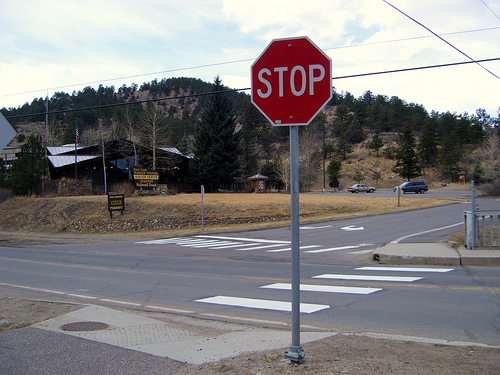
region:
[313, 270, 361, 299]
this is a zebra crossing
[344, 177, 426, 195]
cars on the road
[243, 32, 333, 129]
this is a sign post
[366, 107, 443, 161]
these are some trees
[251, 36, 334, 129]
the signpost is octagonal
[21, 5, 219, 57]
this is the sky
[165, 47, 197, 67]
the sky is blue in color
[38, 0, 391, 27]
the sky has clouds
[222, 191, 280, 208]
the ground is sandy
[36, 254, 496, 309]
the road is clear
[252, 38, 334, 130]
a red octagonal stop sign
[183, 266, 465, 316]
a cross walk painted white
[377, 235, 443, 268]
a cement curb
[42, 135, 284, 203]
a building across the street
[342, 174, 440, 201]
two cars in a parking lot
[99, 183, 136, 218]
a sign on the side of the road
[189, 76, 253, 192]
a big green pine tree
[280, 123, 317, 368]
a gray metal pole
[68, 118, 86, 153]
an American flag on a pole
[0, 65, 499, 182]
a hill in the background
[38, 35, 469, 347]
intersection in rural area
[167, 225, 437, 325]
thick white stripes on crosswalks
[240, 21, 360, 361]
red and white sign on pole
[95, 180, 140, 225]
small framed sign set into ground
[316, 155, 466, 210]
a couple of parked cars in lot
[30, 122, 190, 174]
triangular pieces of roofing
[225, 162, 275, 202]
informational kiosk at edge of lot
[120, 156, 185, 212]
yellow and black sign in front of building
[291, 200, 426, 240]
white arrows on street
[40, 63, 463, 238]
hill in back of building and lot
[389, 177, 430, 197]
a black car in a distance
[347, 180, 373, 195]
a car driving away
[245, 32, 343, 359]
a big stop sign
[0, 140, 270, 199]
a nice house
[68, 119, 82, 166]
an american flag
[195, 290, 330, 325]
a white line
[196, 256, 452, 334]
a zebra crossing sign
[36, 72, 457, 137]
a hill with trees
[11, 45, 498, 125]
an overhead wire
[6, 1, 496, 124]
a blue sky with some clouds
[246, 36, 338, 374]
a stop sign at an intersection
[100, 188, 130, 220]
a small sign in the grass by the road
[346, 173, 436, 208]
two cars parked in a lot in the distance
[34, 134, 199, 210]
a large business building across the street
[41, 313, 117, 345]
a round manhole in the middle of the road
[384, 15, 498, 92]
electrical wires above the road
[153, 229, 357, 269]
white lines for pedestrians in the street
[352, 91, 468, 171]
a green forest of pines in the distance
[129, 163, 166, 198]
a large sign in front of the building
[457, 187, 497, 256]
silver utility poles across the street